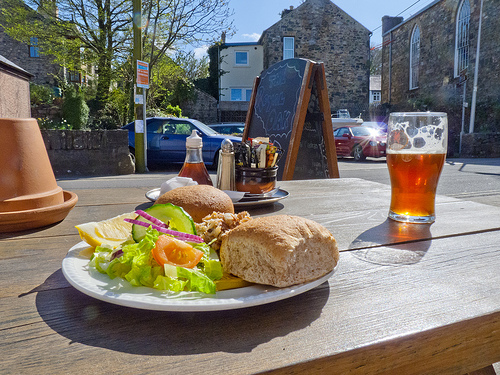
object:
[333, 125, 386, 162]
car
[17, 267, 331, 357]
shadow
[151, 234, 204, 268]
tomato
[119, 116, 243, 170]
blue car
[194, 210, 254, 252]
rolls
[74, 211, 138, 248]
lemon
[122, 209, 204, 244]
purple onion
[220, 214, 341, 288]
bread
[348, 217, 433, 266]
shadow table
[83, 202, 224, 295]
salad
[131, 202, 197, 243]
cucumber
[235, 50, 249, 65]
window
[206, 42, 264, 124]
building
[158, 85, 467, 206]
background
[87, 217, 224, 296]
lettuce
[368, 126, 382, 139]
sun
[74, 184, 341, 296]
food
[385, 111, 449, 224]
glass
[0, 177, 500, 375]
table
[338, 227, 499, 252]
line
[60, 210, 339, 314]
plate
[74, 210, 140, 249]
wedge